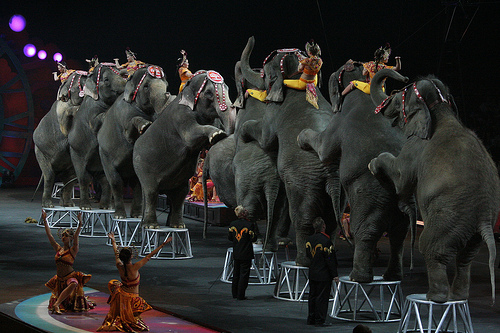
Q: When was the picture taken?
A: During a show.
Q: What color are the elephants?
A: Gray.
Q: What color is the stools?
A: Gray.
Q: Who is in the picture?
A: Performers.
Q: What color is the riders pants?
A: Yellow.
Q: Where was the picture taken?
A: In a stadium.